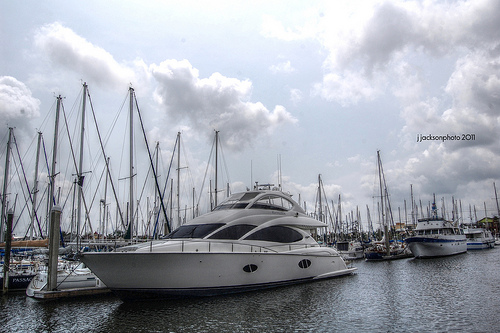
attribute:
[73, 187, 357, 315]
yacht — white